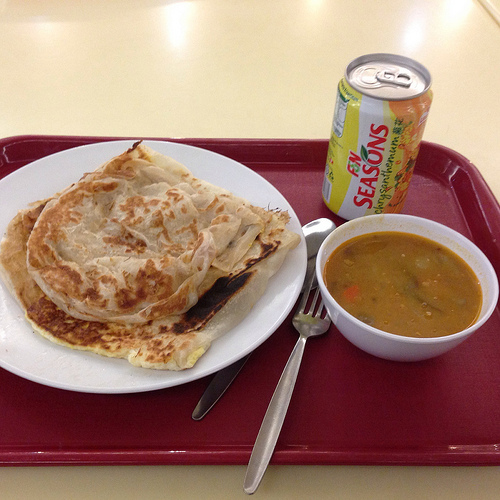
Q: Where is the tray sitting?
A: On the table.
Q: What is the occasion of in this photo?
A: A meal.